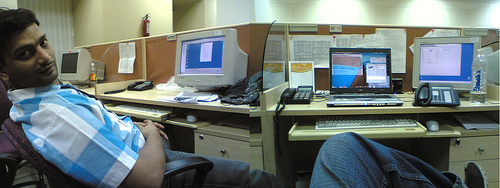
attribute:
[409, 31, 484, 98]
computer — bulky, old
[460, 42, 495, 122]
water bottle — clear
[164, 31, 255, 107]
computer — old, bulky